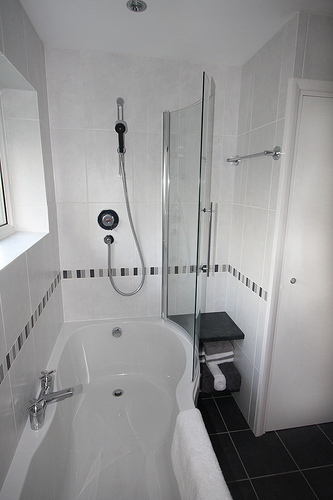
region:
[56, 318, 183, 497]
Very clean looking white bath tub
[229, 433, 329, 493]
Black square floor tiles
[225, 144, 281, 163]
Long silver towel rack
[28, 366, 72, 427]
Stainless water spicket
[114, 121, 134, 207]
Removable Shower head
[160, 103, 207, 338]
Glass curved shower door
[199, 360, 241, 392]
Neatly rolled up towels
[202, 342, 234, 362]
Stack of folded washcloths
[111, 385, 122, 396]
Stainless bathtub stopper and drain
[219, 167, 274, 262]
Large white square wall tiles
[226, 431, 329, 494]
the black tiled floor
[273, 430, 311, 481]
the lighter grout in the black tiling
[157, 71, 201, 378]
the clear glass separator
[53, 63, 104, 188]
the white tiling on the bathroom wall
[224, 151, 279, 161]
the towel rack hanging on the smaller wall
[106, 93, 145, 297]
the hand shower handle and extender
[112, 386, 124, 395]
the silver tub drain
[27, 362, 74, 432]
the silver tub faucet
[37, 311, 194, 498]
the big white tub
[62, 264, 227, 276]
the decorative tile on the wile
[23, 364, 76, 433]
BATH TUB FAUCET FIXTURE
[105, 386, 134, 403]
A BATH TUB DRAIN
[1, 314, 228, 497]
A WHITE BATH TUB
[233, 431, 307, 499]
BLACK FLOOR TILE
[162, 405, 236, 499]
A WHITE BATH MAT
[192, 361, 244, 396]
THREE ROLLED UP TOWELS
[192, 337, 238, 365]
A STACK OF WASH CLOTHS ON A SHELF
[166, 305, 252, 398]
TWO BLACK SHELVES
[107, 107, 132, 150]
A SHOWER HEAD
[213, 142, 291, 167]
A METAL TOWEL ROD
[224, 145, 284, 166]
chrome towel rack is on white wall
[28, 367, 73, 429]
chrome faucet is on white bathtub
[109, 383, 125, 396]
chrome drain is in white bathtub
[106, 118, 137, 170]
black showerhead in on white wall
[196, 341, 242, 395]
rolled towels are below black counter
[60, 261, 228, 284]
multicolored border is on white wall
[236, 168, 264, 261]
white tiles are on wall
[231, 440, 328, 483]
black tiles are on floor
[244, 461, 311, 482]
grouting on floor is white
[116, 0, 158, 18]
metal light fixture in on white ceiling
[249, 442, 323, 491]
this is the floor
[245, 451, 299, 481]
the floor is made of tiles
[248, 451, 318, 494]
the tiles are black in color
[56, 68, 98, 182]
this is the wall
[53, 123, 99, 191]
the wall is made of tiles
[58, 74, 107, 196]
the tiles are white in color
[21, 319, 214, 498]
this is a bath tub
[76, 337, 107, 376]
the bath tub is white in color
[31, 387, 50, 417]
this is a tap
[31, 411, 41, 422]
the tap is metallic